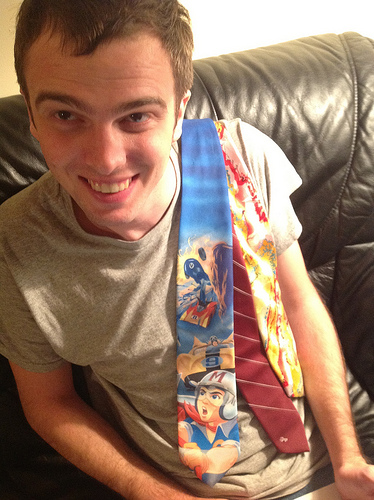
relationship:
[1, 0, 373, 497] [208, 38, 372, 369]
man sitting on couch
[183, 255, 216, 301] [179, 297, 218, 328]
bird in race car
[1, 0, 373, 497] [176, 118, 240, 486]
man with tie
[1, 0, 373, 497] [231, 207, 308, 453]
man with tie